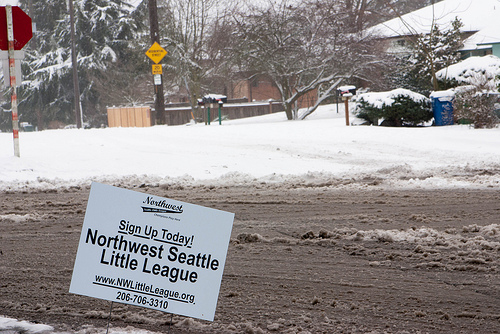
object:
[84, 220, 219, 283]
letters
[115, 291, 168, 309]
number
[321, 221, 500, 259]
slush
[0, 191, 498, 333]
road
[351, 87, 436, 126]
bushes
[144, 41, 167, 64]
sign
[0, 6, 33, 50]
sign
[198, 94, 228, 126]
mailboxes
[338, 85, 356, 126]
mailbox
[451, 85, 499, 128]
bush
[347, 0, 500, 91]
house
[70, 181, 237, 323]
sign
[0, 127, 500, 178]
snow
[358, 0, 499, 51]
rooftop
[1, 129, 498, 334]
ground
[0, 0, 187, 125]
tree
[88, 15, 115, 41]
leaves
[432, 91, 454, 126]
bin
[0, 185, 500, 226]
tracks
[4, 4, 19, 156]
pole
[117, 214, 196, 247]
writing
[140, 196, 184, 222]
logo